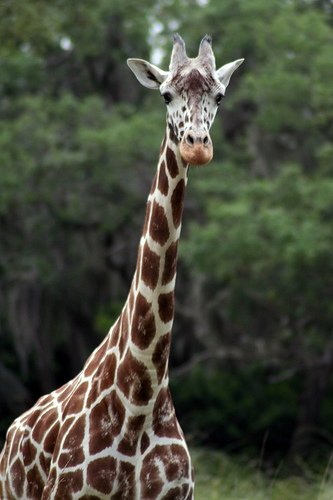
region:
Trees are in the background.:
[6, 6, 329, 412]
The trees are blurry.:
[4, 6, 331, 391]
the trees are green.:
[2, 3, 332, 453]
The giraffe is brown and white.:
[4, 28, 251, 498]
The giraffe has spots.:
[12, 125, 206, 496]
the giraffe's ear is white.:
[120, 47, 171, 101]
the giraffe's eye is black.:
[159, 85, 174, 111]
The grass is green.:
[186, 440, 330, 497]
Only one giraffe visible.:
[0, 25, 245, 497]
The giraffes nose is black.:
[183, 127, 213, 147]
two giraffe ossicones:
[161, 28, 219, 67]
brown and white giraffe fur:
[73, 396, 165, 490]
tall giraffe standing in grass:
[0, 22, 196, 498]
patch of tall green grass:
[210, 457, 268, 497]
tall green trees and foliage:
[245, 36, 331, 485]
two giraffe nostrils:
[181, 130, 209, 148]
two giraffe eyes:
[156, 83, 225, 110]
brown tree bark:
[5, 289, 55, 369]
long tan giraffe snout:
[166, 112, 214, 165]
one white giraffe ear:
[215, 55, 248, 87]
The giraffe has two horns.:
[155, 26, 222, 64]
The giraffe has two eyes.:
[151, 79, 232, 106]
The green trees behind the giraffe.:
[0, 0, 129, 173]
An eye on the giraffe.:
[213, 88, 224, 106]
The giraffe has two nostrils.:
[183, 123, 210, 144]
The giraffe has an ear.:
[116, 48, 171, 87]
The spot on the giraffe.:
[81, 450, 114, 491]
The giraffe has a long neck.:
[117, 150, 193, 340]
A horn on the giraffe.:
[194, 25, 213, 63]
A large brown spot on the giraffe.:
[149, 386, 185, 440]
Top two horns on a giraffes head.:
[169, 34, 215, 65]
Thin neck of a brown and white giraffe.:
[107, 126, 190, 390]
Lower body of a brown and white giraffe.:
[1, 374, 196, 499]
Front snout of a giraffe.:
[180, 128, 215, 166]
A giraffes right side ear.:
[125, 57, 170, 90]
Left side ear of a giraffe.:
[215, 58, 244, 88]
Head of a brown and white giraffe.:
[126, 30, 243, 166]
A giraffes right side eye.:
[158, 91, 173, 104]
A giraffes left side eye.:
[212, 90, 223, 105]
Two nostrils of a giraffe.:
[187, 132, 208, 145]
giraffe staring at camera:
[15, 19, 326, 413]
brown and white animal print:
[70, 410, 138, 474]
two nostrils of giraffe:
[174, 131, 226, 173]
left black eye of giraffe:
[157, 90, 184, 106]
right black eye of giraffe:
[208, 88, 227, 113]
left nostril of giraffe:
[185, 130, 200, 149]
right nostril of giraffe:
[199, 134, 209, 147]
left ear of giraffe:
[123, 54, 166, 89]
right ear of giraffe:
[219, 55, 241, 89]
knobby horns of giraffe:
[154, 28, 220, 69]